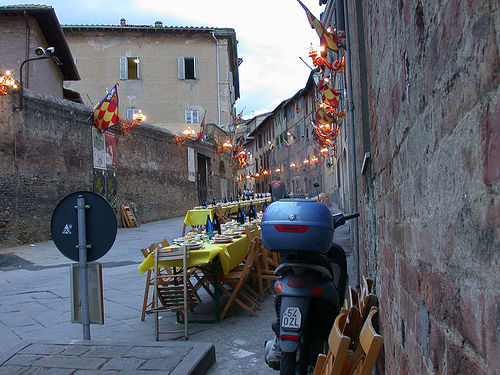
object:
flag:
[313, 77, 340, 110]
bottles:
[205, 213, 216, 237]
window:
[126, 108, 132, 123]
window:
[184, 107, 192, 123]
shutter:
[190, 55, 197, 79]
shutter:
[176, 55, 186, 82]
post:
[75, 197, 89, 341]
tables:
[137, 211, 259, 324]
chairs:
[209, 237, 264, 320]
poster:
[104, 130, 118, 166]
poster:
[184, 147, 197, 183]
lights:
[299, 155, 310, 165]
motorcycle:
[253, 199, 359, 374]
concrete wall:
[0, 84, 240, 250]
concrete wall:
[67, 33, 229, 124]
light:
[129, 55, 141, 66]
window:
[118, 56, 130, 81]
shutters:
[117, 56, 127, 80]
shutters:
[136, 56, 141, 78]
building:
[58, 17, 243, 134]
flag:
[298, 2, 342, 55]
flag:
[195, 110, 206, 145]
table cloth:
[137, 212, 261, 275]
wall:
[358, 0, 498, 374]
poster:
[90, 126, 107, 170]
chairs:
[349, 307, 383, 375]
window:
[190, 55, 200, 82]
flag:
[87, 83, 120, 133]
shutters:
[124, 106, 132, 118]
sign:
[48, 189, 119, 264]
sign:
[68, 263, 104, 326]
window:
[191, 109, 199, 125]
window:
[134, 55, 142, 78]